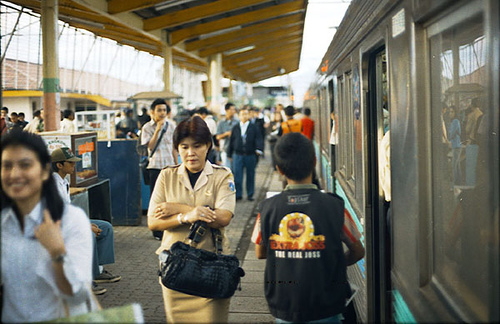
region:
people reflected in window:
[441, 90, 488, 181]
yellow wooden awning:
[1, 1, 303, 87]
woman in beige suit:
[141, 109, 241, 321]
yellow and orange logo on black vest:
[266, 205, 330, 265]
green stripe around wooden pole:
[38, 0, 61, 127]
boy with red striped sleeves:
[251, 128, 367, 322]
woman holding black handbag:
[153, 201, 245, 301]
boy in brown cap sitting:
[44, 144, 123, 298]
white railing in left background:
[69, 105, 118, 137]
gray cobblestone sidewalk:
[70, 116, 278, 322]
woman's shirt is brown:
[149, 165, 240, 242]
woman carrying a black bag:
[143, 115, 255, 300]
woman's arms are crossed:
[145, 190, 241, 231]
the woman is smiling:
[0, 117, 119, 322]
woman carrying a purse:
[2, 130, 152, 320]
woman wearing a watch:
[47, 240, 73, 273]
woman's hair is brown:
[170, 108, 215, 155]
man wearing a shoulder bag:
[135, 96, 184, 181]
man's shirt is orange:
[273, 117, 300, 137]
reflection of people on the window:
[440, 90, 497, 213]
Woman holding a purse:
[156, 200, 245, 300]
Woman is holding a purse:
[153, 204, 246, 301]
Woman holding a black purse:
[155, 207, 244, 299]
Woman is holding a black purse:
[151, 200, 247, 302]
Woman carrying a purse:
[155, 201, 247, 298]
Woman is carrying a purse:
[155, 202, 245, 299]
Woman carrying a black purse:
[157, 200, 244, 298]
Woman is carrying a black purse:
[158, 205, 245, 300]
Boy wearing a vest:
[259, 185, 356, 319]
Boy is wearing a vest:
[255, 187, 352, 319]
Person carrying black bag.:
[177, 205, 239, 304]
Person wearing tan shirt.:
[162, 169, 225, 242]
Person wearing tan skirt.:
[163, 290, 188, 317]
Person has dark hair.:
[172, 121, 201, 151]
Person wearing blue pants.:
[98, 226, 121, 268]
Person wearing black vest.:
[262, 200, 344, 314]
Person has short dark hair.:
[277, 138, 331, 189]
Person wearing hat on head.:
[54, 140, 81, 182]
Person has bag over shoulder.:
[126, 100, 170, 197]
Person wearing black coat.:
[228, 125, 273, 161]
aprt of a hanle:
[216, 235, 245, 261]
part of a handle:
[196, 223, 231, 255]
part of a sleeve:
[204, 165, 256, 224]